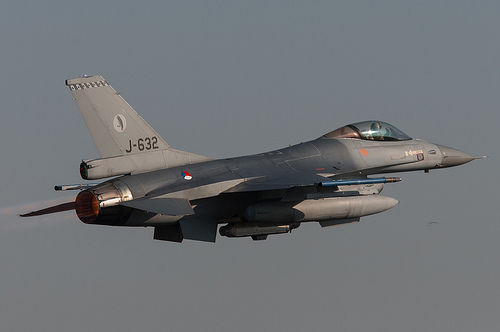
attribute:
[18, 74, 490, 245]
jet — gray, flying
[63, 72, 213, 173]
tail — gray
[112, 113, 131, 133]
circle — white, logo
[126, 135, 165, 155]
writing — black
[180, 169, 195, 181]
marking — red, white, blue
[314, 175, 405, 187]
weapon — missel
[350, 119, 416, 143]
hatch — clear, cockpit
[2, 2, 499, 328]
sky — gray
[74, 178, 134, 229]
engine — glowing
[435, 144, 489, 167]
nose — pointy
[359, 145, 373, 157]
spot — red